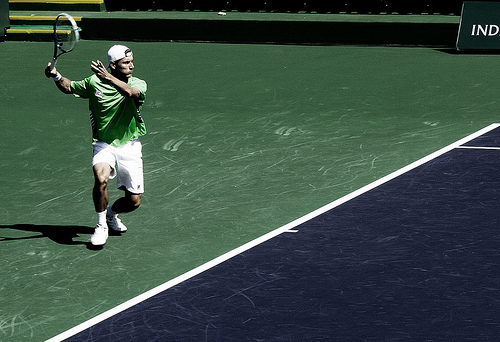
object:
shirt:
[68, 69, 148, 147]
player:
[43, 39, 166, 251]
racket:
[44, 12, 81, 80]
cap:
[101, 43, 134, 68]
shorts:
[86, 137, 146, 196]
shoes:
[84, 219, 111, 250]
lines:
[215, 205, 334, 263]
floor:
[138, 161, 354, 338]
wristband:
[50, 71, 63, 84]